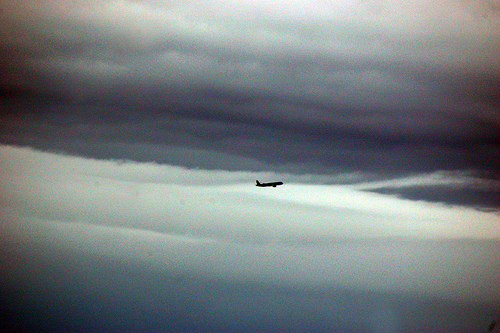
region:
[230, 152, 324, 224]
an far aero plane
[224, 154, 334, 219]
an aeroplane in sky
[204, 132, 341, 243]
a aero plane flying in air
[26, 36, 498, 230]
a beautiful view of sky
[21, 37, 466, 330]
a plane flying near to sky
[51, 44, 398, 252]
a plane flying near to clouds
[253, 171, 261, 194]
back part of the plane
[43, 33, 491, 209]
a beautiful view of clouds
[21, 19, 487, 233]
a clear black clouds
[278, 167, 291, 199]
front part of the plane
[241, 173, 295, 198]
an airplane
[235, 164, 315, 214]
the airplane is in the sky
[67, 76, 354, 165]
the dark clouds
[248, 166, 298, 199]
the airplane is flying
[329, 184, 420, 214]
a white cloud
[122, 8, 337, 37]
the clouds are white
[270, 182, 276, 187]
the wing of the airplane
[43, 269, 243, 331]
the clouds are very dark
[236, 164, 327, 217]
the plane is flying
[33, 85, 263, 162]
the dark clouds are in the sky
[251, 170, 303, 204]
a plane in the sky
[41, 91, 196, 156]
the dark clouds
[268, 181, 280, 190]
the wing of a plane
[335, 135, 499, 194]
the white cloud in the sky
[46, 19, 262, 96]
the clouds are very dark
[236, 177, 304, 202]
the plane is flying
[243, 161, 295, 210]
the plane is in the air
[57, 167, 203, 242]
the white clouds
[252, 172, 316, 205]
the plane is in the air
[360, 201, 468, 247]
the cloud is white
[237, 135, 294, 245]
airplane flying in the sky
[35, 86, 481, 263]
airplane flying on a cloudy day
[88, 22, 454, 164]
grayish rain clouds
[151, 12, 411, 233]
grayish rain clouds above a plane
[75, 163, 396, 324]
plane flying in a cloud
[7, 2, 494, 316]
plane flying amidst a rain storm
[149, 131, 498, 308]
plane in the middle of the sky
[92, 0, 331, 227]
plane flying into the clouds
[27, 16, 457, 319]
plane flying among the clouds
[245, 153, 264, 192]
tail part of the plane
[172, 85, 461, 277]
an airplane in the sky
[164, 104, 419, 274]
an airplane high in the sky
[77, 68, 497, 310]
an airplane flying in the sky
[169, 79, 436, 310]
an airplane flying in the air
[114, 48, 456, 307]
a plane is high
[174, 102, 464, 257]
a plan is flying high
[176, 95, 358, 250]
a plane is flying in the sky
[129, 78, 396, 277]
a plane is high above the ground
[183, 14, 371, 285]
an airplane far away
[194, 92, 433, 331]
a plane far away